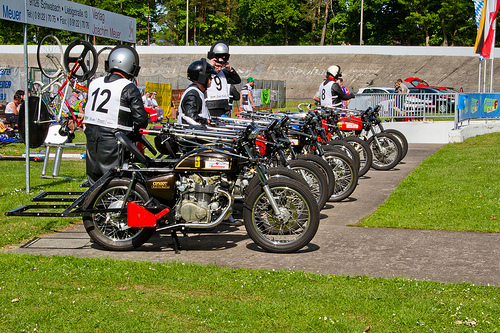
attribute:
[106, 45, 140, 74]
helmet — gray, black, silver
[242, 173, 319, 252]
tire — black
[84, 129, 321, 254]
motorcycle — black, first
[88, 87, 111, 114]
number — black, 12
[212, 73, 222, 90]
number — black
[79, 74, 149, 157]
coat — black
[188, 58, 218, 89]
helmet — black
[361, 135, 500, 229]
grass — patch, green, small area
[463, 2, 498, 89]
flags — far right, different, red, white, black, a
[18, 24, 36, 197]
pole — gray, metal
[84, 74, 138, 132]
vest — white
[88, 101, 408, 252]
motorcycles — lined up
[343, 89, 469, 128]
fence — metal, gate, silver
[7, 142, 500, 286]
path — gray, sidewalk, cement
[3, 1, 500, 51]
trees — green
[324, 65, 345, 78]
helmet — white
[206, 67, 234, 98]
vest — white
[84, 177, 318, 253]
wheels — black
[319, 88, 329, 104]
number — 8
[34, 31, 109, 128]
bikes — hanging, upside down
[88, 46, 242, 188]
people — standing